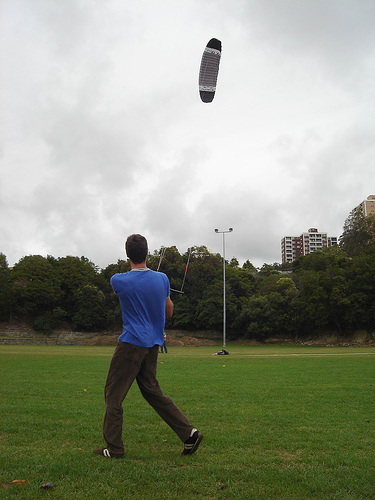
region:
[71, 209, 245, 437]
a man in blue shirt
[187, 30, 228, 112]
a kite in the sky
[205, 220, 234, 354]
a light pole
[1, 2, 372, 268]
a cloudy sky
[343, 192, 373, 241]
a red brick building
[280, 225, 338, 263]
a tall white building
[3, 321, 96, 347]
a stone wall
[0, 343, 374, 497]
a grassy green field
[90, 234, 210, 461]
a man flying a kite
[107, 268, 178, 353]
a blue shirt on a man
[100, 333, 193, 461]
brown pants on a man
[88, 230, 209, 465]
a young man standing in grass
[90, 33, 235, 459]
a young man flying a kite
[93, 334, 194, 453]
a pair of men's brown jeans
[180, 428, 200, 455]
a man's black and white shoe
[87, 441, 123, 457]
a man's black and white shoe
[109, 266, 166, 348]
a dark blue t-shirt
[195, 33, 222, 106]
a grey black and white kite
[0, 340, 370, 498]
a green gassy field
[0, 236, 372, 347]
a line of green trees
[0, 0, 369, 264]
a cloudy white sky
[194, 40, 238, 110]
kite in the sky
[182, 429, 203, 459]
Man wearing black shoes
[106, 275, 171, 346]
Man wearing blue shirt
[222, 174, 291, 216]
The sky is cloudy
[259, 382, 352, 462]
Grass is green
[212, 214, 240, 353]
Light pole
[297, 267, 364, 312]
Green tall bushes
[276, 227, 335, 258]
Buildings in the background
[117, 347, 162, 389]
Man is wearing brown pants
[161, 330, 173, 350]
A person standing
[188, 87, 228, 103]
Large kite flying in the sky.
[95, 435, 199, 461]
Person wearing black and white shoes.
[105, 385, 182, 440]
Person wearing black pants.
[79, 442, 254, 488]
Person standing in grassy area.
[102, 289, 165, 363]
Person wearing blue shirt.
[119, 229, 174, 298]
Person has dark hair.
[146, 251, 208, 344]
Person holding on to long wires.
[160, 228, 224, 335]
Long wires attached to kite in sky.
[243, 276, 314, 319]
Green leaves on trees.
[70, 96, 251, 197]
Sky is full of clouds.